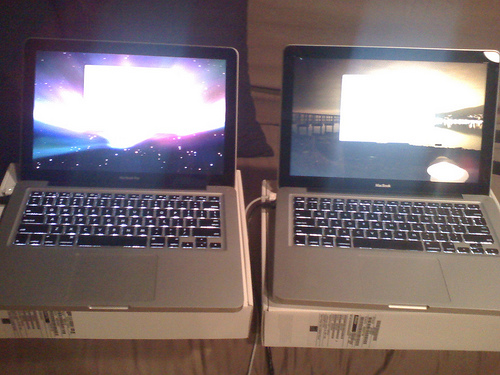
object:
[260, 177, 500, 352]
box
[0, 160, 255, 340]
box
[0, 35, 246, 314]
computer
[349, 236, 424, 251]
space bar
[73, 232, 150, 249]
space bar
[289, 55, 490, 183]
monitor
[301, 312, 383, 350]
sticker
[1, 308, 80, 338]
sticker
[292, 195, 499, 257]
keyboard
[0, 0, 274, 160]
pillow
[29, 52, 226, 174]
display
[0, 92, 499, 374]
table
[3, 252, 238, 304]
laptops on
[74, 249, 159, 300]
mousepad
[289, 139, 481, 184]
beach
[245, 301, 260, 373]
cord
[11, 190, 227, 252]
keyboard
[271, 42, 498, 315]
laptop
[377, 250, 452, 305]
pad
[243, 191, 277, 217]
cord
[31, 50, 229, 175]
laptop screen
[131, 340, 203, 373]
paneling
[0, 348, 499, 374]
cabinet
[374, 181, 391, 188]
brand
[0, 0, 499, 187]
background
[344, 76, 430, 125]
white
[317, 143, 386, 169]
grey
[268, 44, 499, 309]
these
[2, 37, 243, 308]
these